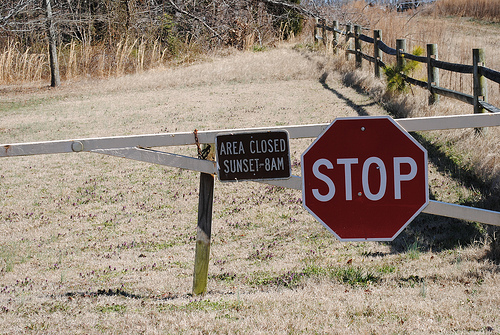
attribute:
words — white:
[219, 137, 287, 174]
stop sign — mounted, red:
[299, 112, 434, 242]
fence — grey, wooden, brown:
[312, 17, 499, 115]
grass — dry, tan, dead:
[307, 44, 382, 95]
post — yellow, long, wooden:
[192, 138, 216, 300]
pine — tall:
[1, 1, 109, 86]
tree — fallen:
[170, 2, 236, 49]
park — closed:
[2, 3, 498, 334]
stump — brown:
[239, 31, 257, 55]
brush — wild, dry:
[2, 40, 172, 83]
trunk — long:
[45, 43, 63, 89]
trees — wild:
[2, 2, 301, 93]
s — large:
[312, 157, 336, 203]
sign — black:
[212, 132, 297, 186]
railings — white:
[5, 109, 499, 290]